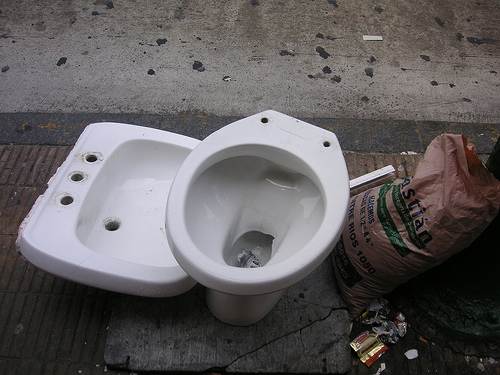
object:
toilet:
[163, 109, 351, 327]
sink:
[18, 121, 200, 299]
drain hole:
[103, 217, 121, 232]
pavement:
[5, 61, 94, 189]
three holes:
[58, 153, 98, 206]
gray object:
[237, 247, 260, 268]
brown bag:
[331, 133, 500, 322]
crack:
[261, 219, 278, 249]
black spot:
[54, 56, 68, 67]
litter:
[348, 293, 409, 368]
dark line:
[0, 111, 500, 155]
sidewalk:
[6, 7, 499, 191]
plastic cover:
[349, 332, 386, 365]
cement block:
[102, 294, 352, 375]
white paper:
[362, 34, 383, 41]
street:
[6, 28, 495, 109]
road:
[71, 37, 485, 117]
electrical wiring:
[409, 325, 432, 345]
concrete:
[9, 36, 491, 86]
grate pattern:
[0, 145, 71, 187]